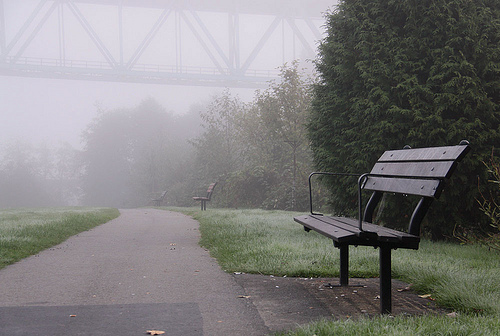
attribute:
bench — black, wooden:
[296, 139, 473, 314]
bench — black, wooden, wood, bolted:
[194, 178, 221, 210]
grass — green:
[141, 205, 499, 335]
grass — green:
[0, 208, 118, 270]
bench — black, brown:
[153, 191, 167, 205]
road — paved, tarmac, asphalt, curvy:
[3, 205, 272, 333]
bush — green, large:
[309, 2, 499, 241]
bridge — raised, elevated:
[3, 1, 341, 85]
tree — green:
[256, 59, 322, 215]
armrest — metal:
[307, 171, 363, 216]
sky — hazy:
[4, 4, 347, 171]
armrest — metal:
[355, 172, 443, 233]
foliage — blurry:
[84, 103, 193, 206]